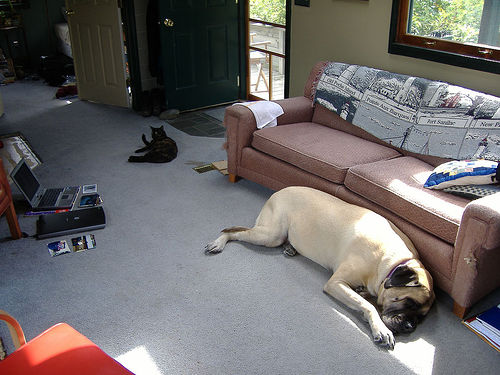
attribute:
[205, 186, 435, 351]
dog — tan, huge, sleeping, blonde, lying down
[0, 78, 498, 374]
carpet — gray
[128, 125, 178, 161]
cat — brown, sleeping, black, lying down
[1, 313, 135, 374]
chair — red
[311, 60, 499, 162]
throw — spread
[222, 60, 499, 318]
couch — tan, pink, brown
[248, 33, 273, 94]
chair — wooden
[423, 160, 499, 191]
pillow — white, blue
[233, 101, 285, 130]
towel — white, hanging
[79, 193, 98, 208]
cd case — blue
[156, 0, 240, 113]
door — open, green, painted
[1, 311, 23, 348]
arm — wooden